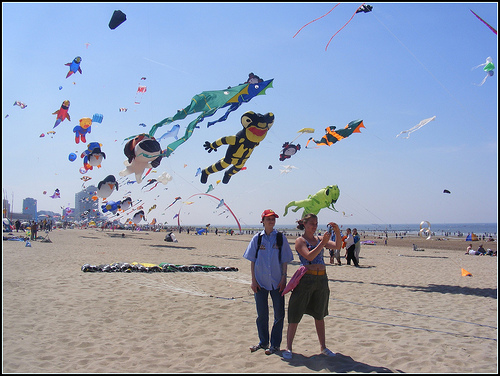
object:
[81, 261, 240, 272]
kite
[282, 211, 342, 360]
lady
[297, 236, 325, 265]
shirt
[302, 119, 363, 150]
kite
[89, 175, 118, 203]
kite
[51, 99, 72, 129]
kite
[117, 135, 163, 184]
kite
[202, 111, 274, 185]
kite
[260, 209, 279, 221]
baseball hat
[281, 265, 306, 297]
pink scarf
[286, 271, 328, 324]
green shorts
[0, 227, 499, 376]
sand